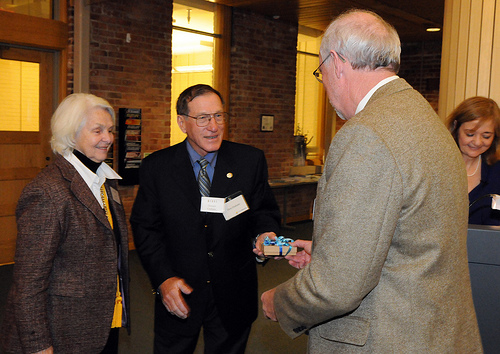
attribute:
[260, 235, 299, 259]
gift — wrapped, being given, small, tan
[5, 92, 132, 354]
woman — smiling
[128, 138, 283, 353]
suit — black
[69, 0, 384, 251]
wall — brick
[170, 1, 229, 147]
window — in the back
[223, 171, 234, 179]
button — gold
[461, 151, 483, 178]
necklace — pearl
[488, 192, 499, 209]
tag — white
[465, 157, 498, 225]
shirt — collared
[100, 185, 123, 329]
tassels — yellow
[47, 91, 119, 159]
hair — gray, white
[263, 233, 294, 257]
ribbon — blue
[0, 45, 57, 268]
door — wooden, brown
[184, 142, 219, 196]
shirt — blue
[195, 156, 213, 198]
tie — striped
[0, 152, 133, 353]
jacket — brown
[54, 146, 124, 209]
shirt — white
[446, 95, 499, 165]
hair — brown